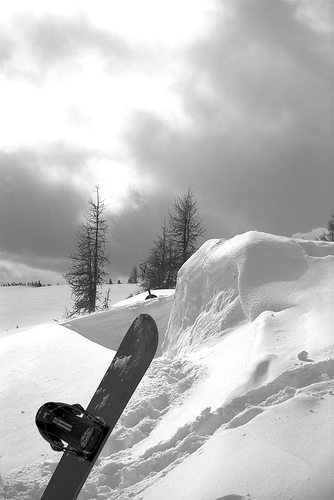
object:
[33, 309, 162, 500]
snowboard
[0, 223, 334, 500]
snow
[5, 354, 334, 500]
tracks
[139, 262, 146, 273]
handle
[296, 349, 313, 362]
clump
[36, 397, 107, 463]
strap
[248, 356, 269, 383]
foot prints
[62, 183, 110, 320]
trees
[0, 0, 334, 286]
clouds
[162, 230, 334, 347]
hill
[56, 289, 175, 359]
shadow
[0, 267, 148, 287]
forest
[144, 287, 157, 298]
shovel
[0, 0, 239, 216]
sun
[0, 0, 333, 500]
landscape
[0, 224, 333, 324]
ridge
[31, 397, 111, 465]
boot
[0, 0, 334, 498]
photograph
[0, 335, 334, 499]
sets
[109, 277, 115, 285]
trees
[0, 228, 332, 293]
horizon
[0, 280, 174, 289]
line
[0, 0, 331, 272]
skies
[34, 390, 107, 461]
holder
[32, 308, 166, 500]
something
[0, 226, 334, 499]
bank